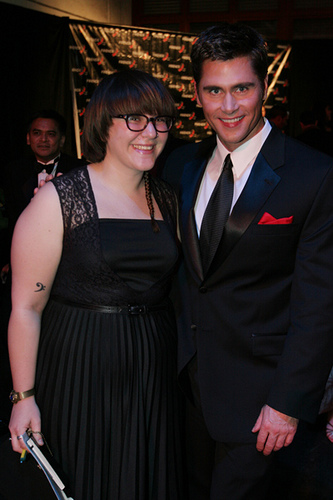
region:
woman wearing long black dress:
[9, 67, 180, 496]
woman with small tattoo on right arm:
[8, 70, 186, 496]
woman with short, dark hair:
[13, 70, 195, 496]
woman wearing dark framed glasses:
[4, 68, 180, 497]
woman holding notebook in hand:
[9, 69, 203, 493]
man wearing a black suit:
[166, 21, 331, 489]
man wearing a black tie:
[163, 24, 331, 485]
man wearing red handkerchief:
[163, 22, 330, 495]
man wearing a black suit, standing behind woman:
[0, 103, 86, 239]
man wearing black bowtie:
[0, 109, 86, 245]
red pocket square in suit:
[259, 211, 294, 221]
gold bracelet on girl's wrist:
[8, 389, 34, 405]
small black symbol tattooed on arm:
[35, 281, 44, 291]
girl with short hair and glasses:
[79, 60, 168, 175]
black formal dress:
[53, 169, 175, 498]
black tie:
[212, 149, 230, 260]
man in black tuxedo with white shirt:
[180, 21, 317, 499]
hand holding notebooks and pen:
[4, 397, 68, 498]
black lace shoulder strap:
[54, 171, 94, 223]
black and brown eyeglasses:
[107, 112, 174, 132]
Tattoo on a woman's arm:
[25, 266, 49, 301]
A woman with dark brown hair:
[74, 59, 184, 185]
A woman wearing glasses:
[94, 75, 181, 175]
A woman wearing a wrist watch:
[4, 377, 44, 407]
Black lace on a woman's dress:
[45, 163, 114, 243]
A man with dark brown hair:
[186, 32, 280, 151]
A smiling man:
[181, 29, 287, 153]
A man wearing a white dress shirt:
[181, 51, 274, 204]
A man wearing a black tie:
[200, 135, 240, 259]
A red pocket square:
[245, 187, 307, 260]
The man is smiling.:
[165, 8, 331, 498]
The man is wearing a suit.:
[167, 15, 332, 498]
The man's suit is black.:
[164, 29, 331, 498]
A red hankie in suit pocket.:
[179, 120, 332, 288]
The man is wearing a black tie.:
[176, 16, 319, 290]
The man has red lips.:
[178, 18, 291, 148]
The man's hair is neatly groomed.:
[178, 15, 290, 148]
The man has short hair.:
[181, 18, 278, 162]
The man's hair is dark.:
[183, 16, 282, 147]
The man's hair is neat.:
[180, 12, 296, 156]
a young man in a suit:
[160, 28, 325, 493]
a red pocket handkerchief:
[253, 209, 293, 224]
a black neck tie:
[197, 154, 233, 262]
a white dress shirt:
[189, 125, 273, 256]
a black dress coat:
[169, 134, 321, 417]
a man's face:
[189, 36, 267, 142]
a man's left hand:
[252, 406, 295, 453]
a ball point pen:
[18, 445, 25, 464]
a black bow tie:
[32, 160, 54, 174]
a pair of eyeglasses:
[108, 110, 175, 134]